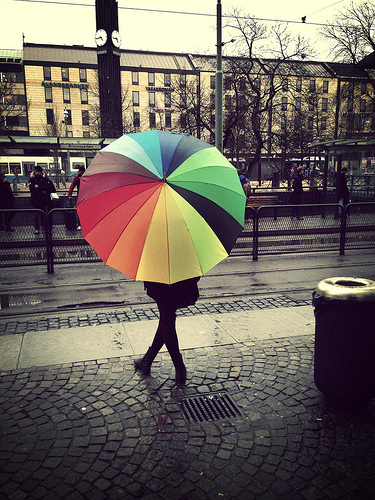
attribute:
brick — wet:
[109, 387, 130, 402]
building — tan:
[0, 29, 357, 147]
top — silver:
[314, 274, 374, 299]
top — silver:
[304, 261, 372, 378]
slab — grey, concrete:
[11, 320, 309, 366]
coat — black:
[26, 173, 56, 208]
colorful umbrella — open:
[74, 129, 245, 283]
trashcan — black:
[310, 266, 374, 406]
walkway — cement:
[30, 315, 323, 463]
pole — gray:
[207, 1, 227, 154]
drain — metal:
[174, 390, 244, 425]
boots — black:
[170, 352, 188, 383]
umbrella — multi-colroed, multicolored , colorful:
[73, 128, 247, 284]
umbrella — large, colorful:
[66, 109, 275, 285]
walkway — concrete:
[5, 292, 370, 498]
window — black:
[131, 69, 140, 85]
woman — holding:
[130, 270, 200, 380]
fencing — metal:
[10, 200, 368, 272]